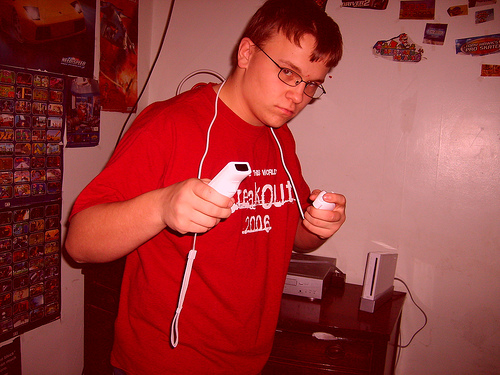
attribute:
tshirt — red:
[121, 106, 285, 291]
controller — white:
[183, 153, 268, 239]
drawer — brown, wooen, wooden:
[286, 297, 386, 371]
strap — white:
[171, 253, 193, 350]